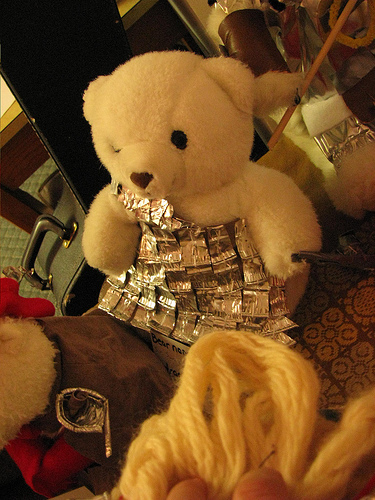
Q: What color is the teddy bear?
A: White.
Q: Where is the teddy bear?
A: On the ground.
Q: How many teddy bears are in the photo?
A: One.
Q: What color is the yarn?
A: Yellow.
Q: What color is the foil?
A: Silver.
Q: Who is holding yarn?
A: A person.